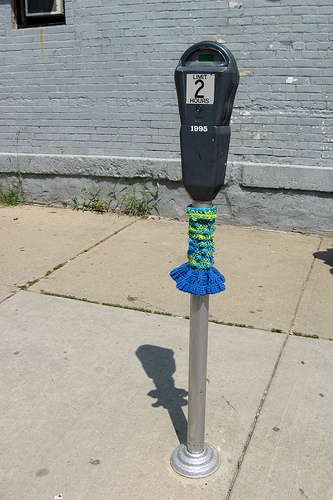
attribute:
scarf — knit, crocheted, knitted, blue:
[175, 207, 228, 298]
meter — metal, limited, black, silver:
[172, 42, 240, 479]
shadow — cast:
[139, 346, 191, 445]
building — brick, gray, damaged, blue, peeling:
[1, 2, 331, 239]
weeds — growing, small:
[3, 179, 155, 219]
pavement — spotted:
[1, 204, 331, 497]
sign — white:
[186, 73, 216, 105]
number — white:
[190, 124, 209, 134]